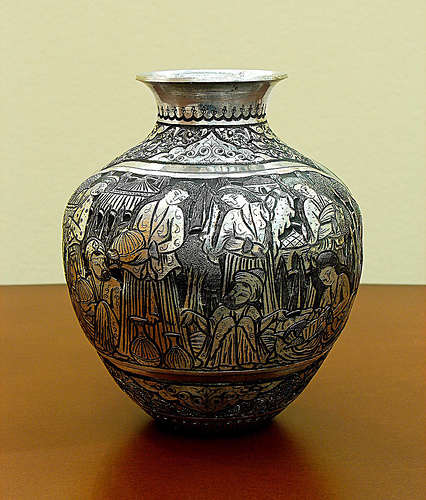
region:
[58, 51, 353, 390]
ASIAN POTTERY WITH DRAWINGS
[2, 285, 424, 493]
BROWN TABLE UNDER VASE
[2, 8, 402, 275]
CREAM COLORED WALL IN BACKGOUND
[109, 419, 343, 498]
SHADOW OF VASE CAST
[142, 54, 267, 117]
LIP OF VASE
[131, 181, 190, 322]
ASIAN INSCRIPTION OF WOMAN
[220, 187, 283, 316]
ASIAN INSCRIPTION OF WOMAN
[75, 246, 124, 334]
ASIAN INSCRIPTION OF MAN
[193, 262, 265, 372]
ASIAN INSCRIPTION OF MAN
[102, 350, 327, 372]
RING AOUND CERAMIC VASE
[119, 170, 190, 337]
woman on a pot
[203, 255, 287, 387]
man sitting on floor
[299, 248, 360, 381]
woman cleaning things on ground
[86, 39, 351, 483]
metal etched vase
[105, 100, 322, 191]
swirl designs on neck of vase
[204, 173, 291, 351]
woman standing above man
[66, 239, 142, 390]
man sitting with pot in hand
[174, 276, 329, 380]
man with arms out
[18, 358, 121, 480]
wood table top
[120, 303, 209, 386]
pots on the ground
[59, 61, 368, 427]
an ornate black and white vase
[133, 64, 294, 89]
the mouth of a vase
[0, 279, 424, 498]
a brown wooden table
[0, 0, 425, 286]
a white wall behind the vase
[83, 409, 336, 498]
a shadow on the table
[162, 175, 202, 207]
a head on the vase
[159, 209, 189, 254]
an arm on the vase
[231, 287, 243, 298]
a nose on the vase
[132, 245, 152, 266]
a hand on the vase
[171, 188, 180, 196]
an eye on the vase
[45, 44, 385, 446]
A large metal vase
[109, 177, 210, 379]
woman holding a vase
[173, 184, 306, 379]
man on ground in front of woman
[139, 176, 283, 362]
two women looking at the man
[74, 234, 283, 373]
man looking at other man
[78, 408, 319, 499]
red reflection on table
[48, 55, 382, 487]
Vase sits on table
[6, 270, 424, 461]
table is brown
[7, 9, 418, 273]
wall is white behind vase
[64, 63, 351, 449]
vase has many people on it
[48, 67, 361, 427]
an intricate silver vase with black etchings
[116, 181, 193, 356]
a drawing of a woman on the vase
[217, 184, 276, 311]
a drawing of a woman on the vase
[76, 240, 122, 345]
a drawing of a man on the vase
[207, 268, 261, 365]
a drawing of a man on the vase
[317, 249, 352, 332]
a drawing of a woman on the vase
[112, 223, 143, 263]
a drawing of a vase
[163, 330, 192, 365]
a drawing of a vase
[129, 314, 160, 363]
a drawing of a vase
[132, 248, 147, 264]
a drawing of a hand